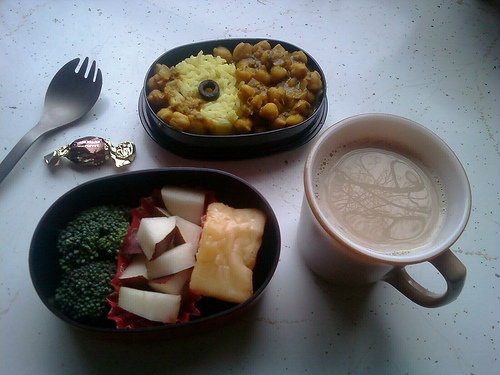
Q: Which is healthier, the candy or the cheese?
A: The cheese is healthier than the candy.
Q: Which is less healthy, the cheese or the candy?
A: The candy is less healthy than the cheese.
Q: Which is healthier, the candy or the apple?
A: The apple is healthier than the candy.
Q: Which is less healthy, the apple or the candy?
A: The candy is less healthy than the apple.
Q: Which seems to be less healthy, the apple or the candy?
A: The candy is less healthy than the apple.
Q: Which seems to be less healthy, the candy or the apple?
A: The candy is less healthy than the apple.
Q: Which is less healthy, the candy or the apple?
A: The candy is less healthy than the apple.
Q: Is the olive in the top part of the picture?
A: Yes, the olive is in the top of the image.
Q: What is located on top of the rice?
A: The olive is on top of the rice.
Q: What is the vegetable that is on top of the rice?
A: The vegetable is an olive.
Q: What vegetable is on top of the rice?
A: The vegetable is an olive.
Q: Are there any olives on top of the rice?
A: Yes, there is an olive on top of the rice.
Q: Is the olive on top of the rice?
A: Yes, the olive is on top of the rice.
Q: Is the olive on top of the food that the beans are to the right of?
A: Yes, the olive is on top of the rice.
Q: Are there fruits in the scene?
A: Yes, there is a fruit.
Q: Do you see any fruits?
A: Yes, there is a fruit.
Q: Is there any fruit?
A: Yes, there is a fruit.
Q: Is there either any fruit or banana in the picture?
A: Yes, there is a fruit.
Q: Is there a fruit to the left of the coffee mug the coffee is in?
A: Yes, there is a fruit to the left of the coffee mug.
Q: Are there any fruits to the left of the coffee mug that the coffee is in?
A: Yes, there is a fruit to the left of the coffee mug.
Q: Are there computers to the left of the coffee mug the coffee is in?
A: No, there is a fruit to the left of the coffee mug.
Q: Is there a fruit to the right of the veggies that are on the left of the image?
A: Yes, there is a fruit to the right of the vegetables.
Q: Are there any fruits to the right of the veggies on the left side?
A: Yes, there is a fruit to the right of the vegetables.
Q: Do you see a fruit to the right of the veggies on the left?
A: Yes, there is a fruit to the right of the vegetables.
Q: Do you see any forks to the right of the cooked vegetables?
A: No, there is a fruit to the right of the vegetables.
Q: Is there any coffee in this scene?
A: Yes, there is coffee.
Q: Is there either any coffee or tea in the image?
A: Yes, there is coffee.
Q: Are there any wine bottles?
A: No, there are no wine bottles.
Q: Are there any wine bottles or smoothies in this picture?
A: No, there are no wine bottles or smoothies.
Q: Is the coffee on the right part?
A: Yes, the coffee is on the right of the image.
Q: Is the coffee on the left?
A: No, the coffee is on the right of the image.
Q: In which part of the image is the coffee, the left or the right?
A: The coffee is on the right of the image.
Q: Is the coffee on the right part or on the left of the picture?
A: The coffee is on the right of the image.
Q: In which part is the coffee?
A: The coffee is on the right of the image.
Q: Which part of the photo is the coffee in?
A: The coffee is on the right of the image.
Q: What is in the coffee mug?
A: The coffee is in the coffee mug.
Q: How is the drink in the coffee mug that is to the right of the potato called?
A: The drink is coffee.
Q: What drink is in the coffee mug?
A: The drink is coffee.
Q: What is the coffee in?
A: The coffee is in the coffee mug.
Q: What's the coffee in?
A: The coffee is in the coffee mug.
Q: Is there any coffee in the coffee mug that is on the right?
A: Yes, there is coffee in the coffee mug.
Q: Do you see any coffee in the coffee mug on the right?
A: Yes, there is coffee in the coffee mug.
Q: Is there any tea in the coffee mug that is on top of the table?
A: No, there is coffee in the coffee mug.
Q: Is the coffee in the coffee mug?
A: Yes, the coffee is in the coffee mug.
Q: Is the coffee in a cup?
A: No, the coffee is in the coffee mug.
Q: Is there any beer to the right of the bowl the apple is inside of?
A: No, there is coffee to the right of the bowl.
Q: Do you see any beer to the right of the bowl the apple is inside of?
A: No, there is coffee to the right of the bowl.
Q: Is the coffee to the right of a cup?
A: No, the coffee is to the right of the bowl.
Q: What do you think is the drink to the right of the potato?
A: The drink is coffee.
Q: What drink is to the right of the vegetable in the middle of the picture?
A: The drink is coffee.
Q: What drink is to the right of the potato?
A: The drink is coffee.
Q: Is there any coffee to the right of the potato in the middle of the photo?
A: Yes, there is coffee to the right of the potato.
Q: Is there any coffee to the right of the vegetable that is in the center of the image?
A: Yes, there is coffee to the right of the potato.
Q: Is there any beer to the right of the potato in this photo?
A: No, there is coffee to the right of the potato.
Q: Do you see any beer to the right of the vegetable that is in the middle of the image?
A: No, there is coffee to the right of the potato.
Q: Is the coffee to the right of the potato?
A: Yes, the coffee is to the right of the potato.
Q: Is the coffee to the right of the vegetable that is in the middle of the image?
A: Yes, the coffee is to the right of the potato.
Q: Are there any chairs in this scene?
A: No, there are no chairs.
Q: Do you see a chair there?
A: No, there are no chairs.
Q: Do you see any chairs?
A: No, there are no chairs.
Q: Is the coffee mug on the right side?
A: Yes, the coffee mug is on the right of the image.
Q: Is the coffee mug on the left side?
A: No, the coffee mug is on the right of the image.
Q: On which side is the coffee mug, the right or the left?
A: The coffee mug is on the right of the image.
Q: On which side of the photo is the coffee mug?
A: The coffee mug is on the right of the image.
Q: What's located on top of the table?
A: The coffee mug is on top of the table.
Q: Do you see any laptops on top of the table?
A: No, there is a coffee mug on top of the table.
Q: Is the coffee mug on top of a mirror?
A: No, the coffee mug is on top of the table.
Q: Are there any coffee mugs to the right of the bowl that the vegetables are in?
A: Yes, there is a coffee mug to the right of the bowl.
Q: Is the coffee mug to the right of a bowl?
A: Yes, the coffee mug is to the right of a bowl.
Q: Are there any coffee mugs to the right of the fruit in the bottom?
A: Yes, there is a coffee mug to the right of the fruit.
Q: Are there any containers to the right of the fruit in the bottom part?
A: No, there is a coffee mug to the right of the fruit.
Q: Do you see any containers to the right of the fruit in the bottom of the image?
A: No, there is a coffee mug to the right of the fruit.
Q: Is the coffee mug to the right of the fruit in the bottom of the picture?
A: Yes, the coffee mug is to the right of the fruit.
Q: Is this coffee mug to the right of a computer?
A: No, the coffee mug is to the right of the fruit.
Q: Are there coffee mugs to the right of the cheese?
A: Yes, there is a coffee mug to the right of the cheese.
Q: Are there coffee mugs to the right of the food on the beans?
A: Yes, there is a coffee mug to the right of the cheese.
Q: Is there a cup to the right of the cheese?
A: No, there is a coffee mug to the right of the cheese.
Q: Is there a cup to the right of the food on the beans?
A: No, there is a coffee mug to the right of the cheese.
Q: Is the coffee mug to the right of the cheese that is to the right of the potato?
A: Yes, the coffee mug is to the right of the cheese.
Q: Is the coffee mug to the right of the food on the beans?
A: Yes, the coffee mug is to the right of the cheese.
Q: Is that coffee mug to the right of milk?
A: No, the coffee mug is to the right of the cheese.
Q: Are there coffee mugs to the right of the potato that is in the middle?
A: Yes, there is a coffee mug to the right of the potato.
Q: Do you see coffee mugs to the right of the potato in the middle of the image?
A: Yes, there is a coffee mug to the right of the potato.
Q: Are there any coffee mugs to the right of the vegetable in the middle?
A: Yes, there is a coffee mug to the right of the potato.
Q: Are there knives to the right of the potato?
A: No, there is a coffee mug to the right of the potato.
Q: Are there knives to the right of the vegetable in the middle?
A: No, there is a coffee mug to the right of the potato.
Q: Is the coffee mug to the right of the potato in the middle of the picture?
A: Yes, the coffee mug is to the right of the potato.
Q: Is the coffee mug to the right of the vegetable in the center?
A: Yes, the coffee mug is to the right of the potato.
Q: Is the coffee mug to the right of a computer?
A: No, the coffee mug is to the right of the potato.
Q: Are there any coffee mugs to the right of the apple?
A: Yes, there is a coffee mug to the right of the apple.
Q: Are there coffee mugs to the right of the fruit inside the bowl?
A: Yes, there is a coffee mug to the right of the apple.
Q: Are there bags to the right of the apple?
A: No, there is a coffee mug to the right of the apple.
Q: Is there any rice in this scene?
A: Yes, there is rice.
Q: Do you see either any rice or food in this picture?
A: Yes, there is rice.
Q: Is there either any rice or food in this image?
A: Yes, there is rice.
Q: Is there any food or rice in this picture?
A: Yes, there is rice.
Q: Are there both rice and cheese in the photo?
A: Yes, there are both rice and cheese.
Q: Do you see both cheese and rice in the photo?
A: Yes, there are both rice and cheese.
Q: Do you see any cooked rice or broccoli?
A: Yes, there is cooked rice.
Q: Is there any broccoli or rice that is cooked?
A: Yes, the rice is cooked.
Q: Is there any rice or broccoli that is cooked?
A: Yes, the rice is cooked.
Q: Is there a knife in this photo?
A: No, there are no knives.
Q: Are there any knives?
A: No, there are no knives.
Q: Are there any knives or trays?
A: No, there are no knives or trays.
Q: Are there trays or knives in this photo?
A: No, there are no knives or trays.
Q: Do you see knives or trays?
A: No, there are no knives or trays.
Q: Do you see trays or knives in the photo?
A: No, there are no knives or trays.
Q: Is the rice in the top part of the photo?
A: Yes, the rice is in the top of the image.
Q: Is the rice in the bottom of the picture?
A: No, the rice is in the top of the image.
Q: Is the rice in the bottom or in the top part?
A: The rice is in the top of the image.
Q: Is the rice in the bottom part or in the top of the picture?
A: The rice is in the top of the image.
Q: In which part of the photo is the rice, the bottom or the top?
A: The rice is in the top of the image.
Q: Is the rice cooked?
A: Yes, the rice is cooked.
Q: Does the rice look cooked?
A: Yes, the rice is cooked.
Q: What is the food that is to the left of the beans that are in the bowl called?
A: The food is rice.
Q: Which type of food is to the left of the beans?
A: The food is rice.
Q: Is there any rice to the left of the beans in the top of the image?
A: Yes, there is rice to the left of the beans.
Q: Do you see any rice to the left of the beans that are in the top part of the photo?
A: Yes, there is rice to the left of the beans.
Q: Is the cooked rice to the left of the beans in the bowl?
A: Yes, the rice is to the left of the beans.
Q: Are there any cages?
A: No, there are no cages.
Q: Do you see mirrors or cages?
A: No, there are no cages or mirrors.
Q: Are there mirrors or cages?
A: No, there are no cages or mirrors.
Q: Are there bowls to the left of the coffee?
A: Yes, there is a bowl to the left of the coffee.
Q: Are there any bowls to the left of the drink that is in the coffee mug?
A: Yes, there is a bowl to the left of the coffee.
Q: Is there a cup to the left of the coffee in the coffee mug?
A: No, there is a bowl to the left of the coffee.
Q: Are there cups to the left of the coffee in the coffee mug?
A: No, there is a bowl to the left of the coffee.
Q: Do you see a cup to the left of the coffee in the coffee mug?
A: No, there is a bowl to the left of the coffee.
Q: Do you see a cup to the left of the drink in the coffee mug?
A: No, there is a bowl to the left of the coffee.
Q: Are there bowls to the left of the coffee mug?
A: Yes, there is a bowl to the left of the coffee mug.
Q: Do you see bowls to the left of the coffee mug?
A: Yes, there is a bowl to the left of the coffee mug.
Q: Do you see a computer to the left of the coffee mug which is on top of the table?
A: No, there is a bowl to the left of the coffee mug.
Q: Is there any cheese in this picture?
A: Yes, there is cheese.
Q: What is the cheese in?
A: The cheese is in the bowl.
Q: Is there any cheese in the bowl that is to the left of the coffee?
A: Yes, there is cheese in the bowl.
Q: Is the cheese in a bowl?
A: Yes, the cheese is in a bowl.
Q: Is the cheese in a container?
A: No, the cheese is in a bowl.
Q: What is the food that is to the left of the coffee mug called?
A: The food is cheese.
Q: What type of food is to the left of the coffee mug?
A: The food is cheese.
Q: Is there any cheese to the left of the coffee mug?
A: Yes, there is cheese to the left of the coffee mug.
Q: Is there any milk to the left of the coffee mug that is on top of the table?
A: No, there is cheese to the left of the coffee mug.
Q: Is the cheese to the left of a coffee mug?
A: Yes, the cheese is to the left of a coffee mug.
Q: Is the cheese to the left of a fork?
A: No, the cheese is to the left of a coffee mug.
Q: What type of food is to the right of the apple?
A: The food is cheese.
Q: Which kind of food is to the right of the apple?
A: The food is cheese.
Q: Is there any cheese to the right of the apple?
A: Yes, there is cheese to the right of the apple.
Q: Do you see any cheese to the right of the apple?
A: Yes, there is cheese to the right of the apple.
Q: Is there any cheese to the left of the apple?
A: No, the cheese is to the right of the apple.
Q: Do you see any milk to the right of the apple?
A: No, there is cheese to the right of the apple.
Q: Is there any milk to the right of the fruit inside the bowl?
A: No, there is cheese to the right of the apple.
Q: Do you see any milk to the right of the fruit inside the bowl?
A: No, there is cheese to the right of the apple.